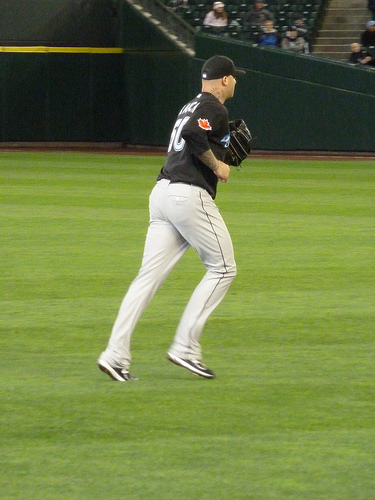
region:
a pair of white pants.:
[98, 177, 237, 373]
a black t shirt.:
[152, 93, 237, 197]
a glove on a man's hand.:
[209, 107, 259, 176]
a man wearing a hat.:
[195, 44, 249, 112]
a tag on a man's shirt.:
[187, 117, 218, 148]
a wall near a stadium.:
[0, 53, 373, 158]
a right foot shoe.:
[160, 338, 223, 387]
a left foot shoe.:
[93, 349, 142, 395]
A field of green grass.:
[0, 155, 372, 496]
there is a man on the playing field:
[89, 45, 267, 401]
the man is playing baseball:
[92, 46, 260, 385]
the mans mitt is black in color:
[222, 113, 254, 166]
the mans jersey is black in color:
[155, 90, 236, 190]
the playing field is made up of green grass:
[25, 152, 121, 318]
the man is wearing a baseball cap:
[193, 51, 248, 83]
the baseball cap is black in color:
[195, 45, 244, 87]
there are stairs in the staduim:
[313, 5, 366, 69]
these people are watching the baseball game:
[190, 1, 371, 72]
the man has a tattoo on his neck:
[204, 84, 226, 103]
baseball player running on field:
[103, 43, 238, 384]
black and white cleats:
[97, 347, 212, 379]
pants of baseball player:
[105, 169, 234, 360]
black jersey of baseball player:
[151, 85, 236, 191]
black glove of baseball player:
[223, 120, 259, 169]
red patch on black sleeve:
[191, 116, 217, 133]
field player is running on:
[8, 152, 355, 486]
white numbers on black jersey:
[165, 119, 191, 153]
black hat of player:
[194, 56, 242, 75]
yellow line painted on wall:
[1, 44, 116, 56]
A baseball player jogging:
[93, 51, 249, 381]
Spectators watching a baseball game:
[197, 0, 365, 61]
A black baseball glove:
[217, 112, 247, 161]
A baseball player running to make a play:
[90, 48, 244, 378]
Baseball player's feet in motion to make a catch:
[90, 336, 210, 371]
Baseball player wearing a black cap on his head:
[196, 50, 241, 95]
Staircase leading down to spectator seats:
[304, 0, 364, 60]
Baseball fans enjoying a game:
[198, 0, 365, 67]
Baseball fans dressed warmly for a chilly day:
[200, 0, 369, 62]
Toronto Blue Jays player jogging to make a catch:
[93, 52, 252, 382]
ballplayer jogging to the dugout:
[98, 56, 253, 382]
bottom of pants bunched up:
[168, 335, 203, 360]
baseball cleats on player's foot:
[163, 351, 214, 378]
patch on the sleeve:
[194, 119, 214, 130]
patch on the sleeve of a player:
[198, 118, 210, 129]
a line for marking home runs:
[0, 46, 128, 54]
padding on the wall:
[195, 34, 374, 151]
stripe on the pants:
[185, 187, 227, 358]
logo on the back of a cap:
[200, 73, 207, 79]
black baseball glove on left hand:
[220, 118, 251, 166]